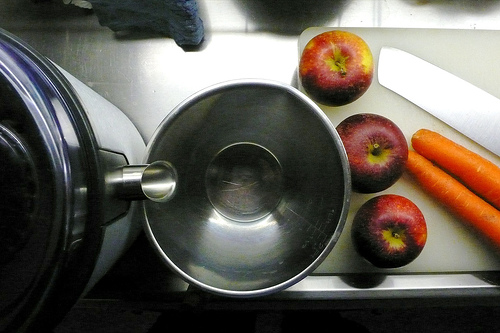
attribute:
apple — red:
[339, 113, 406, 193]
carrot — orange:
[411, 127, 499, 195]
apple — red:
[352, 194, 428, 268]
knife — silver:
[374, 45, 500, 155]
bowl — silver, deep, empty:
[130, 77, 357, 304]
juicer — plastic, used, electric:
[3, 30, 158, 317]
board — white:
[295, 23, 500, 275]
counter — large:
[2, 1, 500, 289]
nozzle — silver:
[103, 148, 177, 219]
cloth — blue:
[92, 2, 213, 52]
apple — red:
[299, 29, 372, 106]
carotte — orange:
[411, 127, 499, 195]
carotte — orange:
[406, 155, 499, 241]